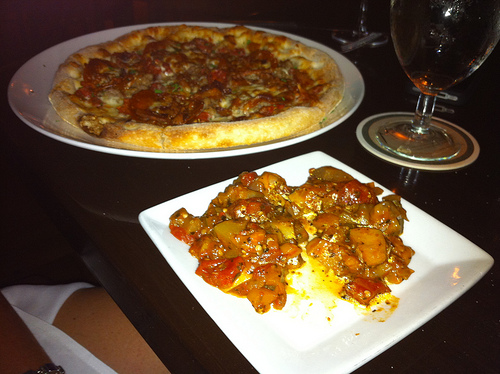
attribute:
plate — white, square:
[137, 151, 495, 372]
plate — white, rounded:
[9, 21, 367, 161]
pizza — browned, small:
[50, 23, 345, 155]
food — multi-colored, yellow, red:
[171, 167, 413, 311]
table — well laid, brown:
[9, 3, 498, 372]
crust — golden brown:
[117, 116, 312, 151]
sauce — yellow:
[316, 262, 343, 297]